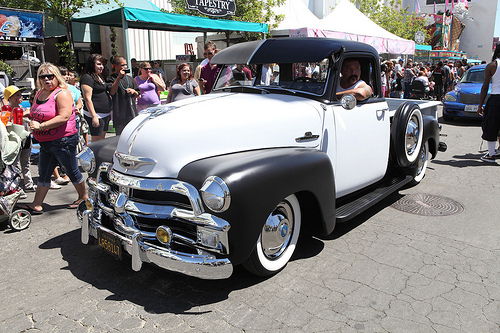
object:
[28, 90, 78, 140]
top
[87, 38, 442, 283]
pickup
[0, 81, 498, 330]
street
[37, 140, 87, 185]
jeans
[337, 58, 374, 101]
man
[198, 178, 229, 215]
headlight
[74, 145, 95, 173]
headlight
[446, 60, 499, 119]
car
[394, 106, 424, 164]
tire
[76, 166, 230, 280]
bumper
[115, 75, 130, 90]
necklace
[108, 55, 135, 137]
man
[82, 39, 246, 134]
group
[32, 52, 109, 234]
woman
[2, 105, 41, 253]
stroller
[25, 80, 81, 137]
shirt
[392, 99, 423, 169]
spare tire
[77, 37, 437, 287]
car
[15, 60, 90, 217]
lady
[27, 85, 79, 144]
pink shirt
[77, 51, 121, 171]
woman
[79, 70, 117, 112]
shirt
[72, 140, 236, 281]
car's front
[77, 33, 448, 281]
older car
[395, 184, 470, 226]
manhole cover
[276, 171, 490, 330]
street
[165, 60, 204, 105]
lady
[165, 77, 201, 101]
shirt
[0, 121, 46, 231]
babystroller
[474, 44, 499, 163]
man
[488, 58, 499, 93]
tank top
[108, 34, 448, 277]
truck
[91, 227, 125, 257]
plate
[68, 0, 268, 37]
awning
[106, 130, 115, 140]
sidewalk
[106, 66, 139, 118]
shirt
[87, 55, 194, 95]
people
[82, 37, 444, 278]
restored truck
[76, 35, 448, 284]
pickup truck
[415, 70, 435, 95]
person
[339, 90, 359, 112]
mirror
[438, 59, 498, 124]
car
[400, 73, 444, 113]
scooter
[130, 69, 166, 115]
shirt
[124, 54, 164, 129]
woman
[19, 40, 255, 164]
people